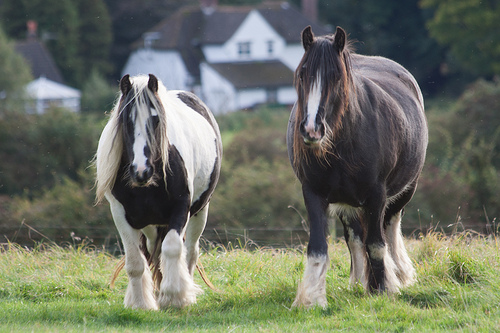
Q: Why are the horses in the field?
A: To exercise.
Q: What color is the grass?
A: Green.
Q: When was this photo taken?
A: During the day.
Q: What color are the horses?
A: White and brown.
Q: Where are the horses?
A: In a field.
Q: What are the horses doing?
A: Walking.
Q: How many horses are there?
A: Two.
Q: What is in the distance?
A: A house.